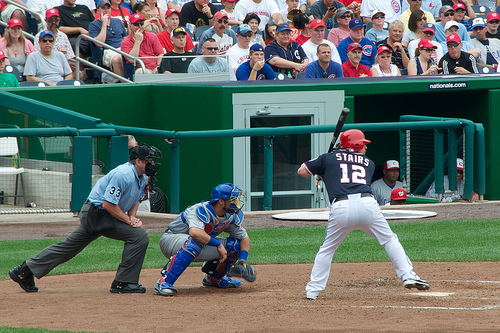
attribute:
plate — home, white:
[399, 288, 458, 302]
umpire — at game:
[8, 143, 164, 295]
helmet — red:
[339, 129, 373, 153]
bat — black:
[314, 105, 352, 191]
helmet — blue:
[207, 182, 233, 208]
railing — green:
[1, 91, 489, 211]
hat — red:
[126, 11, 147, 26]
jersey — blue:
[304, 148, 378, 204]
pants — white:
[306, 191, 422, 294]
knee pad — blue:
[160, 236, 203, 289]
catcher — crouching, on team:
[154, 181, 258, 297]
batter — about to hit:
[296, 126, 431, 303]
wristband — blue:
[205, 235, 222, 249]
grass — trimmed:
[1, 220, 500, 282]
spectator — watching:
[304, 41, 345, 82]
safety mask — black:
[144, 144, 163, 178]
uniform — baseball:
[157, 199, 248, 295]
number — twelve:
[336, 161, 371, 187]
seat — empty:
[54, 79, 88, 88]